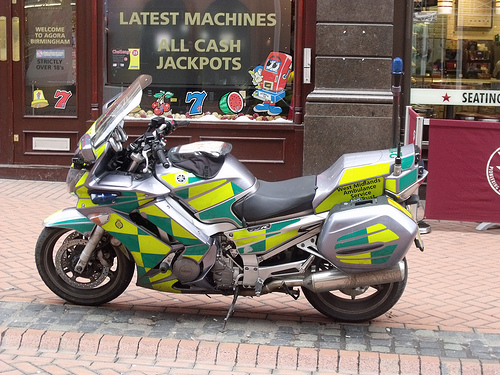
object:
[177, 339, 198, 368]
red brick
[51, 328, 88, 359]
brick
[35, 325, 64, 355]
brick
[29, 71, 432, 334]
bike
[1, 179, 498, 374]
ground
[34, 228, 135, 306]
tire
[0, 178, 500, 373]
road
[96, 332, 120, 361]
brick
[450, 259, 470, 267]
brick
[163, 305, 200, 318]
brick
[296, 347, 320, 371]
brick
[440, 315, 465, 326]
brick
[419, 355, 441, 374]
brick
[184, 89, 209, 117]
number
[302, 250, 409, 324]
back tire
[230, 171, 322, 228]
seat